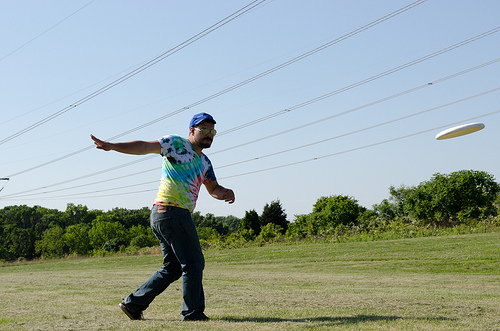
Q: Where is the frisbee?
A: In the air.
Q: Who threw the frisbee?
A: The man.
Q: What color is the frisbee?
A: White.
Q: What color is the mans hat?
A: Blue.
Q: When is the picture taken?
A: Day time.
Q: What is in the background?
A: Trees.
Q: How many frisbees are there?
A: One.